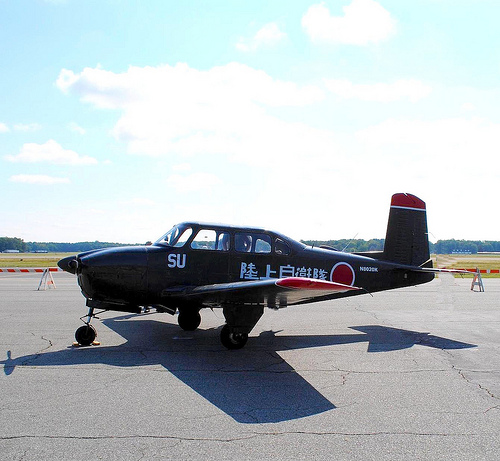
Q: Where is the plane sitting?
A: On concrete.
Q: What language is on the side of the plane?
A: A foreign language.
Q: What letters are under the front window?
A: SU.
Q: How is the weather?
A: Clear with a few clouds.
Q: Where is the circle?
A: On the back of the plane.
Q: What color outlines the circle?
A: White.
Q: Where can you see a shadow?
A: On the concrete.